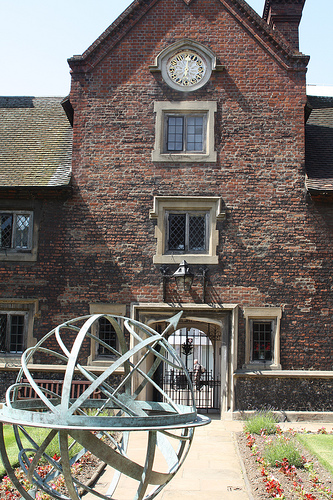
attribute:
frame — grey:
[144, 35, 228, 91]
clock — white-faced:
[167, 49, 207, 84]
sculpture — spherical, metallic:
[8, 307, 214, 494]